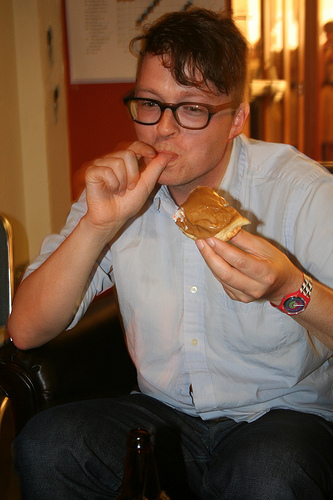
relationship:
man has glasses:
[18, 10, 322, 500] [121, 88, 235, 132]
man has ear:
[18, 10, 322, 500] [231, 102, 254, 138]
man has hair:
[18, 10, 322, 500] [159, 10, 249, 91]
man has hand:
[18, 10, 322, 500] [66, 135, 175, 222]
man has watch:
[18, 10, 322, 500] [274, 269, 322, 319]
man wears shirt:
[18, 10, 322, 500] [96, 172, 322, 420]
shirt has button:
[96, 172, 322, 420] [182, 281, 207, 297]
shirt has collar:
[96, 172, 322, 420] [226, 148, 260, 194]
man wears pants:
[18, 10, 322, 500] [36, 391, 327, 496]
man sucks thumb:
[18, 10, 322, 500] [146, 146, 180, 184]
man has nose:
[18, 10, 322, 500] [157, 109, 179, 143]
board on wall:
[66, 0, 232, 86] [79, 96, 116, 139]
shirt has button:
[96, 172, 322, 420] [183, 336, 206, 349]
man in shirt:
[18, 10, 322, 500] [96, 172, 322, 420]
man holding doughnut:
[18, 10, 322, 500] [163, 184, 252, 251]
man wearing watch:
[18, 10, 322, 500] [274, 269, 322, 319]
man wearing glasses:
[18, 10, 322, 500] [121, 88, 235, 132]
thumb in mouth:
[146, 146, 180, 184] [144, 144, 185, 166]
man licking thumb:
[18, 10, 322, 500] [146, 146, 180, 184]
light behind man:
[239, 0, 267, 47] [18, 10, 322, 500]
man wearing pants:
[18, 10, 322, 500] [36, 391, 327, 496]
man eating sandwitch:
[18, 10, 322, 500] [163, 184, 252, 251]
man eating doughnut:
[18, 10, 322, 500] [163, 184, 252, 251]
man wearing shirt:
[18, 10, 322, 500] [96, 172, 322, 420]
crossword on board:
[126, 0, 209, 62] [61, 0, 232, 94]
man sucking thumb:
[18, 10, 322, 500] [146, 146, 180, 184]